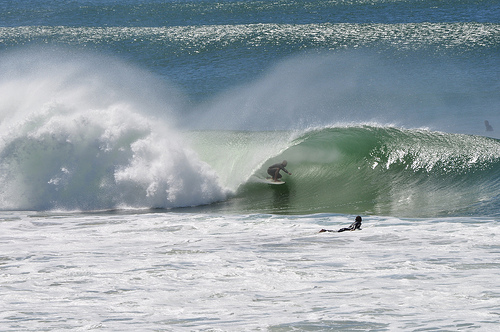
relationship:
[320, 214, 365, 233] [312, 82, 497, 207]
person in front of wave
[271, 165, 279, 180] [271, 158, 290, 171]
leg of surfer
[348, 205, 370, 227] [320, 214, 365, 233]
head of person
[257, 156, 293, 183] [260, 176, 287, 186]
person on surfboard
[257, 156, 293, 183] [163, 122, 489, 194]
person under wave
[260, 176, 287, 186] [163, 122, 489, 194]
surfboard under wave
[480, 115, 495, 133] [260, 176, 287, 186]
person on surfboard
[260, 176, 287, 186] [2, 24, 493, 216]
surfboard behind wave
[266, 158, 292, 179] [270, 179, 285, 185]
man on surfboard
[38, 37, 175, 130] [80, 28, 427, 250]
spray from ocean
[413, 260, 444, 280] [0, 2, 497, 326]
ripples of water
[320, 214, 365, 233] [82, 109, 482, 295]
person on beach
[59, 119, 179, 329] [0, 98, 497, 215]
white foam on wave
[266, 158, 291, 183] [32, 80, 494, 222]
man under wave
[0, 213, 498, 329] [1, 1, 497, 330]
foam in ocean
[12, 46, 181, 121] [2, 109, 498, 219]
mist coming out of wave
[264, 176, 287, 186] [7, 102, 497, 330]
surfboard in water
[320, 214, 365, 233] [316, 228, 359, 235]
person laying on surfboard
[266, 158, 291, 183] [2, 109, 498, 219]
man on wave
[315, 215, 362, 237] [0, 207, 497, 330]
person in surf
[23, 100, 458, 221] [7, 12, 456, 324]
wave in ocean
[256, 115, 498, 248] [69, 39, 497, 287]
two surfers in ocean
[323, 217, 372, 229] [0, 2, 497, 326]
person paddling on water